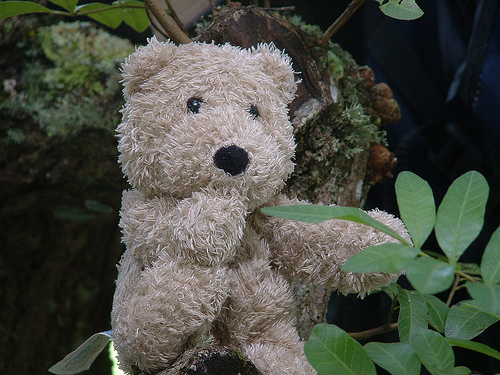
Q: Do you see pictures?
A: No, there are no pictures.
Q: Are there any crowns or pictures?
A: No, there are no pictures or crowns.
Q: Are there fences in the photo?
A: No, there are no fences.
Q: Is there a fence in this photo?
A: No, there are no fences.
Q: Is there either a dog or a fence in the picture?
A: No, there are no fences or dogs.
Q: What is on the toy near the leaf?
A: The tag is on the stuffed animal.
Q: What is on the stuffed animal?
A: The tag is on the stuffed animal.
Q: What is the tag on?
A: The tag is on the stuffed animal.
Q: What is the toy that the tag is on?
A: The toy is a stuffed animal.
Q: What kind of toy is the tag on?
A: The tag is on the stuffed animal.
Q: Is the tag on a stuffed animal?
A: Yes, the tag is on a stuffed animal.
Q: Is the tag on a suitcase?
A: No, the tag is on a stuffed animal.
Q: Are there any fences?
A: No, there are no fences.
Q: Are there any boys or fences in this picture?
A: No, there are no fences or boys.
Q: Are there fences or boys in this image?
A: No, there are no fences or boys.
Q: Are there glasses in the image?
A: No, there are no glasses.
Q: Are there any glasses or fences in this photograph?
A: No, there are no glasses or fences.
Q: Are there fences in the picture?
A: No, there are no fences.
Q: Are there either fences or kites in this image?
A: No, there are no fences or kites.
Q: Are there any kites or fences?
A: No, there are no fences or kites.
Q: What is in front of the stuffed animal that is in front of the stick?
A: The leaf is in front of the stuffed animal.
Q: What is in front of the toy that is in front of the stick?
A: The leaf is in front of the stuffed animal.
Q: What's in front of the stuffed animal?
A: The leaf is in front of the stuffed animal.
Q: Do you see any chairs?
A: No, there are no chairs.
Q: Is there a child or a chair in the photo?
A: No, there are no chairs or children.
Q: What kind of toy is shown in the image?
A: The toy is a stuffed animal.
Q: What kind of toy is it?
A: The toy is a stuffed animal.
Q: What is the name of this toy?
A: That is a stuffed animal.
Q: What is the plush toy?
A: The toy is a stuffed animal.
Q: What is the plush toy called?
A: The toy is a stuffed animal.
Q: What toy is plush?
A: The toy is a stuffed animal.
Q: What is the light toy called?
A: The toy is a stuffed animal.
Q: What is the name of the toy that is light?
A: The toy is a stuffed animal.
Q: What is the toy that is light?
A: The toy is a stuffed animal.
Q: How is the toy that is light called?
A: The toy is a stuffed animal.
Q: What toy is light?
A: The toy is a stuffed animal.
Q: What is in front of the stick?
A: The stuffed animal is in front of the stick.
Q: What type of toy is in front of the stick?
A: The toy is a stuffed animal.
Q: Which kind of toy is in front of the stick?
A: The toy is a stuffed animal.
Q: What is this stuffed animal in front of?
A: The stuffed animal is in front of the stick.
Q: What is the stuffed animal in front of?
A: The stuffed animal is in front of the stick.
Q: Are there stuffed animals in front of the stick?
A: Yes, there is a stuffed animal in front of the stick.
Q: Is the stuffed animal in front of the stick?
A: Yes, the stuffed animal is in front of the stick.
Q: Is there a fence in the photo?
A: No, there are no fences.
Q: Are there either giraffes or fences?
A: No, there are no fences or giraffes.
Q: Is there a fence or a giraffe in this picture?
A: No, there are no fences or giraffes.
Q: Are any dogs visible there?
A: No, there are no dogs.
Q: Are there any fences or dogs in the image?
A: No, there are no dogs or fences.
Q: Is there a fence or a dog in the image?
A: No, there are no dogs or fences.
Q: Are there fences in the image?
A: No, there are no fences.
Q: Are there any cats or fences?
A: No, there are no fences or cats.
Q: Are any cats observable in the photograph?
A: No, there are no cats.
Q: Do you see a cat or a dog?
A: No, there are no cats or dogs.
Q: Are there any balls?
A: No, there are no balls.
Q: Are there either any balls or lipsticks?
A: No, there are no balls or lipsticks.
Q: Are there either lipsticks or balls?
A: No, there are no balls or lipsticks.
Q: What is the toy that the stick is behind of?
A: The toy is a stuffed animal.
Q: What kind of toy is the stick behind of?
A: The stick is behind the stuffed animal.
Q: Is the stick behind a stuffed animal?
A: Yes, the stick is behind a stuffed animal.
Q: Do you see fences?
A: No, there are no fences.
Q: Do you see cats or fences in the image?
A: No, there are no fences or cats.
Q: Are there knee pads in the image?
A: No, there are no knee pads.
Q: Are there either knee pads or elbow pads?
A: No, there are no knee pads or elbow pads.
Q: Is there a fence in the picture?
A: No, there are no fences.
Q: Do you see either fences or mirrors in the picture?
A: No, there are no fences or mirrors.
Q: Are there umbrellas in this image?
A: No, there are no umbrellas.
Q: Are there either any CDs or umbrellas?
A: No, there are no umbrellas or cds.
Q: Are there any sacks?
A: No, there are no sacks.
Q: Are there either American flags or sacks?
A: No, there are no sacks or American flags.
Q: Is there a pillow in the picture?
A: No, there are no pillows.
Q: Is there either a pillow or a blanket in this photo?
A: No, there are no pillows or blankets.